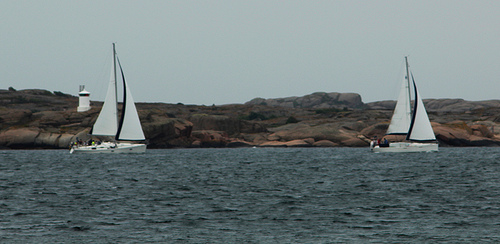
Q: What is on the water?
A: Two sailboats/.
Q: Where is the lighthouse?
A: To the left of the sailboat on the left.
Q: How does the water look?
A: Fairly calm.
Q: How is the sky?
A: Overcast.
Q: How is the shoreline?
A: Rocky.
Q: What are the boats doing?
A: Sailing in the water.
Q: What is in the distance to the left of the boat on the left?
A: A white lighthouse.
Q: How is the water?
A: Rippling.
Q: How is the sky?
A: Cloudy.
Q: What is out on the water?
A: Boats.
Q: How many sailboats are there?
A: Two.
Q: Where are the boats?
A: In the sea.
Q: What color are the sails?
A: White.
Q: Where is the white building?
A: On the shore.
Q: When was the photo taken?
A: During the daytime.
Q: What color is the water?
A: Blue.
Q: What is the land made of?
A: Large rocks.